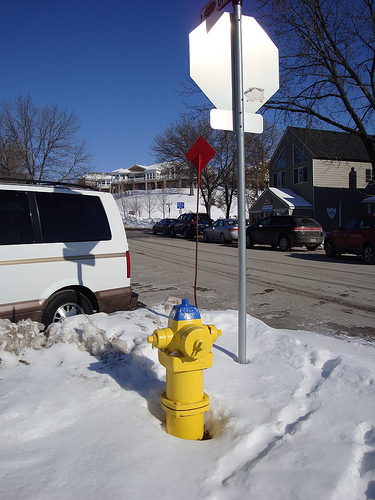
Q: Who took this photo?
A: A tourist.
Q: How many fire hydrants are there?
A: One.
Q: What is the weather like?
A: Cold.